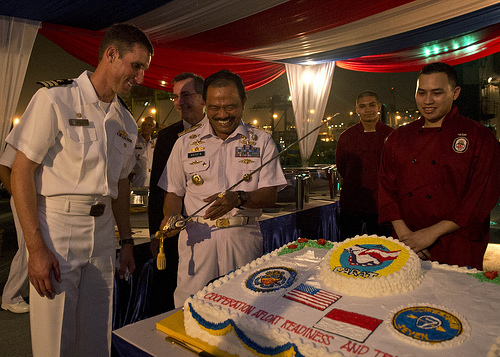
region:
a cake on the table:
[170, 232, 495, 353]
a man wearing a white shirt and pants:
[12, 26, 134, 354]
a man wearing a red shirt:
[376, 62, 493, 249]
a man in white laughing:
[173, 72, 289, 254]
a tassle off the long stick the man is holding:
[153, 227, 170, 269]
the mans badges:
[186, 133, 206, 186]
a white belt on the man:
[36, 195, 115, 214]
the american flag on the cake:
[282, 280, 342, 310]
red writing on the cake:
[203, 288, 398, 355]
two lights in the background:
[291, 66, 331, 91]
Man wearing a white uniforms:
[6, 30, 130, 355]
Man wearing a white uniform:
[158, 67, 288, 307]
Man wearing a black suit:
[146, 74, 218, 289]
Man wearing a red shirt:
[378, 67, 499, 265]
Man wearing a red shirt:
[333, 97, 395, 231]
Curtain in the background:
[276, 60, 332, 165]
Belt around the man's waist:
[37, 189, 115, 224]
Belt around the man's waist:
[180, 213, 259, 238]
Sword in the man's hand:
[155, 109, 347, 241]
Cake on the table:
[177, 228, 498, 355]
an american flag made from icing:
[283, 270, 355, 317]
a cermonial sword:
[136, 105, 358, 240]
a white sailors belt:
[28, 185, 139, 232]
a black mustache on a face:
[211, 115, 243, 125]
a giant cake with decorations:
[186, 182, 471, 344]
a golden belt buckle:
[211, 216, 255, 230]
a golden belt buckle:
[86, 194, 118, 224]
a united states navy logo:
[238, 245, 313, 308]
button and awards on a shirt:
[222, 140, 268, 161]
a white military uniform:
[7, 52, 159, 222]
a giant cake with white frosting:
[185, 240, 498, 355]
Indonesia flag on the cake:
[317, 307, 381, 339]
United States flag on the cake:
[286, 281, 341, 310]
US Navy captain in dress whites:
[12, 27, 152, 350]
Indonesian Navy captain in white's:
[157, 68, 289, 309]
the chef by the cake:
[372, 63, 498, 266]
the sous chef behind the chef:
[339, 94, 391, 231]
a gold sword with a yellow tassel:
[152, 108, 337, 268]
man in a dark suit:
[149, 77, 207, 311]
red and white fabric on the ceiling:
[44, 4, 499, 91]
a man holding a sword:
[154, 113, 336, 270]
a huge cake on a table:
[181, 236, 498, 354]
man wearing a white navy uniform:
[6, 67, 141, 355]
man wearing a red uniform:
[378, 106, 498, 272]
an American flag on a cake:
[283, 279, 340, 309]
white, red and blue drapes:
[0, 0, 499, 162]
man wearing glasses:
[167, 90, 202, 100]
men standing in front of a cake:
[6, 20, 496, 355]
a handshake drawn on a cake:
[346, 243, 401, 268]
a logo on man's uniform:
[453, 135, 469, 154]